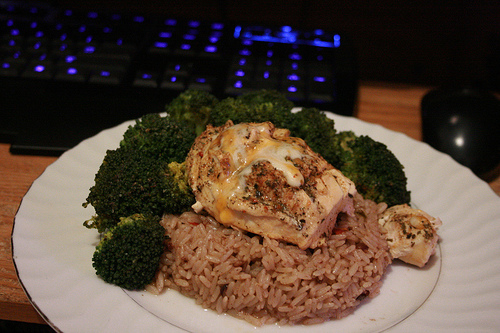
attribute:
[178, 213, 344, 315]
rice — brown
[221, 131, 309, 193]
cheese — melted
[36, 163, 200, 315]
plate — white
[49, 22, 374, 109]
keyboard — black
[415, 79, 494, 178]
mouse — black